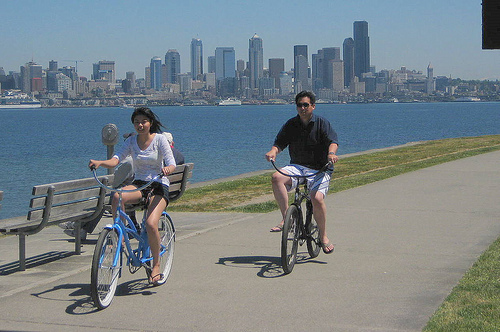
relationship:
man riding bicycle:
[261, 90, 341, 255] [265, 155, 333, 273]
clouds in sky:
[197, 11, 251, 38] [4, 3, 496, 88]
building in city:
[329, 59, 344, 93] [7, 15, 483, 104]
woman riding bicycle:
[88, 106, 177, 284] [86, 159, 178, 309]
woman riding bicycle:
[89, 97, 174, 291] [76, 183, 179, 313]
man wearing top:
[267, 90, 333, 254] [270, 115, 337, 169]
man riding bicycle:
[267, 90, 333, 254] [265, 156, 325, 275]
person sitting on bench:
[161, 131, 188, 173] [3, 159, 195, 261]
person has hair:
[161, 131, 188, 173] [162, 130, 174, 141]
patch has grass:
[164, 139, 494, 215] [180, 133, 498, 206]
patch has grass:
[449, 240, 487, 315] [425, 234, 498, 327]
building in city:
[354, 17, 370, 84] [0, 20, 498, 107]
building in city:
[343, 35, 363, 89] [0, 20, 498, 107]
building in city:
[316, 47, 344, 95] [1, 19, 498, 99]